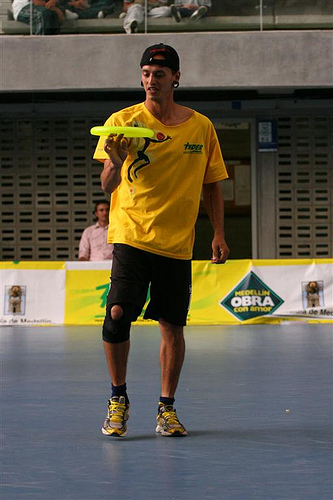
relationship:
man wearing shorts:
[90, 41, 228, 438] [101, 240, 193, 346]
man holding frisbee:
[90, 41, 228, 438] [87, 124, 153, 138]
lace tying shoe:
[107, 396, 126, 422] [101, 394, 131, 437]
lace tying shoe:
[159, 408, 181, 427] [155, 401, 189, 437]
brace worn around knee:
[101, 302, 132, 344] [101, 298, 132, 325]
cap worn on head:
[140, 42, 180, 88] [139, 41, 180, 100]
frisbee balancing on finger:
[87, 124, 153, 138] [105, 131, 117, 141]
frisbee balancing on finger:
[87, 124, 153, 138] [113, 132, 123, 144]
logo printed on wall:
[0, 283, 52, 324] [1, 257, 323, 323]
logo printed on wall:
[93, 279, 152, 319] [1, 257, 323, 323]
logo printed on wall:
[216, 269, 323, 322] [1, 257, 323, 323]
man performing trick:
[90, 41, 228, 438] [87, 40, 229, 437]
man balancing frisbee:
[90, 41, 228, 438] [87, 124, 153, 138]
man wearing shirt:
[90, 41, 228, 438] [91, 99, 229, 259]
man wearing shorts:
[90, 41, 228, 438] [104, 242, 192, 326]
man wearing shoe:
[90, 41, 228, 438] [99, 392, 130, 438]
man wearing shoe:
[90, 41, 228, 438] [154, 400, 186, 436]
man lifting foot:
[90, 41, 228, 438] [99, 392, 131, 438]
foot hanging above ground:
[99, 392, 131, 438] [1, 325, 322, 497]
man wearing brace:
[90, 41, 228, 438] [102, 302, 132, 344]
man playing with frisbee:
[90, 41, 228, 438] [87, 124, 153, 138]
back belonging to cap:
[139, 42, 180, 71] [139, 40, 180, 86]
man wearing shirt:
[76, 199, 114, 260] [77, 222, 112, 260]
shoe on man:
[102, 396, 129, 440] [90, 41, 228, 438]